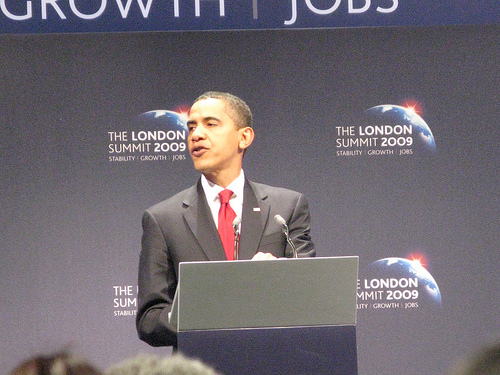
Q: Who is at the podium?
A: Barack Obama.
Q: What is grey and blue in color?
A: A podium.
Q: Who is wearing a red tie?
A: Barack Obama.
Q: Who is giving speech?
A: President.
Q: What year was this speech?
A: 2009.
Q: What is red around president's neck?
A: A tie.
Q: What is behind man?
A: Large banner.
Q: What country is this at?
A: London.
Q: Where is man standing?
A: Podium.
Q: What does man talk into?
A: Microphone.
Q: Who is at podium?
A: Barack obama.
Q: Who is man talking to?
A: The crowd.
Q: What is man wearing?
A: Suit and tie.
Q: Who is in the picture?
A: President of the united states.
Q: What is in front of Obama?
A: A podium.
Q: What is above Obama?
A: Growing jobs banner.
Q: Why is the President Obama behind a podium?
A: He is giving a speech.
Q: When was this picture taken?
A: 2009.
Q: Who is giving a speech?
A: President Obama.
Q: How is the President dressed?
A: In a grey suit.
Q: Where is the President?
A: In London.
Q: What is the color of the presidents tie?
A: Red.